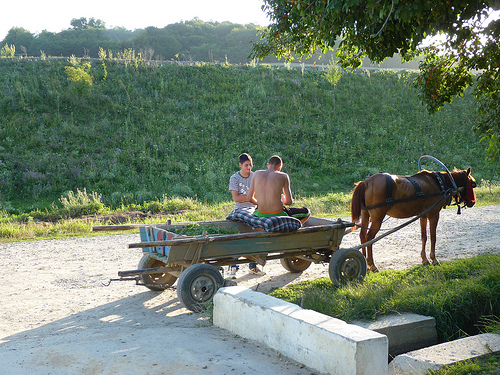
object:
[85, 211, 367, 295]
cart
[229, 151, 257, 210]
men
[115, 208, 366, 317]
wooden cart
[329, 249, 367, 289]
wheel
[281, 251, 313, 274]
wheel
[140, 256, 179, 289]
wheel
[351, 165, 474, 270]
brown horse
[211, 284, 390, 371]
block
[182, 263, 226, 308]
black wheel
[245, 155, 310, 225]
man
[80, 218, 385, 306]
wood wagon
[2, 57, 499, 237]
grassy hill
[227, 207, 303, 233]
checkered cushion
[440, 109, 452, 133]
leafs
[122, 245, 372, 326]
wheels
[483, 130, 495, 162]
leaves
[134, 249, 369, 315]
wheels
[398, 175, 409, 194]
ribs